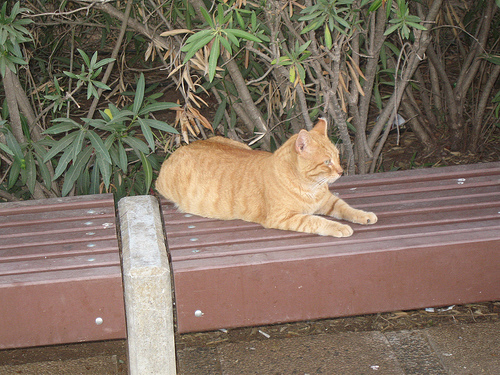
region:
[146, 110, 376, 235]
A red tabby sitting on a bench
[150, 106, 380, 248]
A red tabby sitting on a bench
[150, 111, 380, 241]
A red tabby sitting on a bench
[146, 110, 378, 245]
A red tabby sitting on a bench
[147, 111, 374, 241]
A red tabby sitting on a bench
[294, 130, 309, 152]
The left ear of the cat.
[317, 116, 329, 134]
The right ear of the cat.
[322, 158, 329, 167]
The left eye of the cat.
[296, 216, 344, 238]
The left leg of the cat.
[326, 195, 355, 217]
The right leg of the cat.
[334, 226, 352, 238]
The left paw of the cat.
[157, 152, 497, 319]
The bench where the cat is sitting.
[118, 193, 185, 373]
The cement barrier between the benches.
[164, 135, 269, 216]
The body of the cat.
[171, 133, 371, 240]
the cat is brown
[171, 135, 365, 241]
the cat is siited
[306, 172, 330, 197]
the whiskers are white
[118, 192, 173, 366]
the stone is white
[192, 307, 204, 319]
rivets are on the surface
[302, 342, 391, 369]
the ground is grey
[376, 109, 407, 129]
trash is in the background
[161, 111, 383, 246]
cat sitting on the bench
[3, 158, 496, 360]
two brown benches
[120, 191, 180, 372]
cement divider between benches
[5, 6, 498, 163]
shrubbery behind the park benches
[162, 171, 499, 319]
bench cat is laying on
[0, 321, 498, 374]
pavement underneath the bench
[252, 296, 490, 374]
debris under the bench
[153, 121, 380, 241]
orange cat laying down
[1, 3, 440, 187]
leaves on the shrubbery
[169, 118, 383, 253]
this is a brown cat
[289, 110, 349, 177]
the head of a cat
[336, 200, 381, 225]
the leg of a cat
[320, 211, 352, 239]
the leg of a cat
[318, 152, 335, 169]
the eye of the cat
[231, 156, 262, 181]
the fur of the cat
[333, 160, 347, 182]
the nose of the cat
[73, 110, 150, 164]
these are gree leaves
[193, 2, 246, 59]
these are green leaves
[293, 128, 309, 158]
Ear of a cat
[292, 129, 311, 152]
Ear of a cat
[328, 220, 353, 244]
Paw of a cat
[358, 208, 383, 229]
Paw of a cat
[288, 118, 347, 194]
Head of a cat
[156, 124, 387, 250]
Cat on a bench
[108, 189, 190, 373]
Stone between a bench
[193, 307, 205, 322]
Screw in a bench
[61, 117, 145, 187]
Leaves on a bush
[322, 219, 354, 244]
Paws of a cat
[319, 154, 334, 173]
Eye of a cat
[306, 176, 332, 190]
Wiskers on a cat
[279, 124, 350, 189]
Head of a cat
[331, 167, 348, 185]
Nose of a cat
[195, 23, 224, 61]
green leaves on the tree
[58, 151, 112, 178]
green leaves on the tree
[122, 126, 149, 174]
green leaves on the tree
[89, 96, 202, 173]
green leaves on the tree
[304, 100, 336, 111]
green leaves on the tree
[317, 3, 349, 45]
green leaves on the tree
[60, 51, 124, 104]
green leaves on the tree